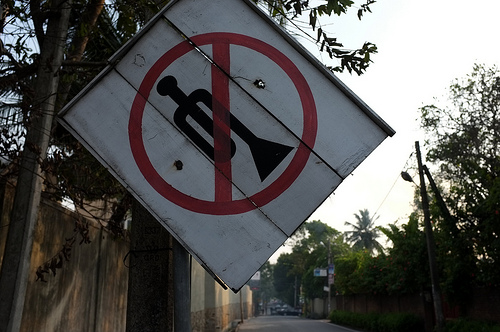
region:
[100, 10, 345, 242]
Sign for no music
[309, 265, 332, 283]
sign on a pole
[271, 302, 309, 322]
Car in the distance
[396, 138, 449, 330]
Electric wire on a pole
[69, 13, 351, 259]
Sign showing no trumpet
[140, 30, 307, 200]
Sign showing no trumpet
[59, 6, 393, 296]
white sign with red and black print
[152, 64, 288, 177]
black trombone printed on sign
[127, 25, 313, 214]
red circle on white sign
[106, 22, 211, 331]
utility pole behind sign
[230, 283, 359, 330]
road beside street sign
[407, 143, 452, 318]
utility pole across the street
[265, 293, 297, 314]
cars up the street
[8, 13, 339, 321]
tree behind street sign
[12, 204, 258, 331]
wall along street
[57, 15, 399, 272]
white sign made of wood planks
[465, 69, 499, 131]
Green parts of a tree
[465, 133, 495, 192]
Green parts of a tree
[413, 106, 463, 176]
Green parts of a tree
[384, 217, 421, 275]
Green parts of a tree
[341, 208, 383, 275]
Green parts of a tree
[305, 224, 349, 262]
Green parts of a tree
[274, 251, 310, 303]
Green parts of a tree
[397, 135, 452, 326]
VEry tall liht post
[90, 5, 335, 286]
Red and white sign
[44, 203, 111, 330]
Part of wooden fence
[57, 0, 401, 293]
a tilted white sign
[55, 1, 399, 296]
a tilted sign with a trumpet on it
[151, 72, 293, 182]
a picture of a black trumpet on the sign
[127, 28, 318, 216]
a red circle with a slash through it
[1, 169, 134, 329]
a wooden fence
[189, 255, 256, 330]
a beige wall on the left side of the street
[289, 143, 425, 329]
power lines on the right side of the street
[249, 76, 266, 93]
a hole in the sign with light showing through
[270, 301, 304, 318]
a black car at the end of the street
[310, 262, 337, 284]
several signs on a pole in the background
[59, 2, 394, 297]
An informational sign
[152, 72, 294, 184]
A picture of a black instrument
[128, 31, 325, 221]
A red no circle on a white sign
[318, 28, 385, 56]
A bunch of green tree leaves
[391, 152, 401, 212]
Electrical wires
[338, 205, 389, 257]
A green palm tree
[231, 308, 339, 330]
A rural road with no cars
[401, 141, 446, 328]
A street light along the side of the road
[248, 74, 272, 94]
A hole in the white boards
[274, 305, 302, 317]
A dark colored car parked in the distance